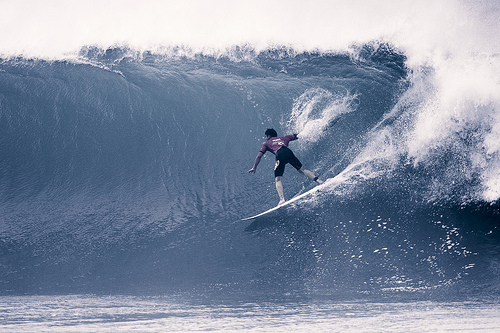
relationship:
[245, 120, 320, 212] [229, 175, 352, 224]
man on surfboard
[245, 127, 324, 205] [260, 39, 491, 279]
man riding wave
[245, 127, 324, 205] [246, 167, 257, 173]
man has hand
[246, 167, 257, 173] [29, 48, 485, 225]
hand inside wave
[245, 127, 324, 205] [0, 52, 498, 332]
man playing in water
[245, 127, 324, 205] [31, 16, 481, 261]
man surfing in ocean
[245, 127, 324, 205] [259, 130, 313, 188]
man wearing suit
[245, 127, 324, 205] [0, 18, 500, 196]
man riding wave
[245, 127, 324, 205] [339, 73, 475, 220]
man touching wave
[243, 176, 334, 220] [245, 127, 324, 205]
surfboard tethered to man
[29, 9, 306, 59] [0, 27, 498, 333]
skies over water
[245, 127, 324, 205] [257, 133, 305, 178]
man wearing suit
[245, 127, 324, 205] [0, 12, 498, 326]
man on wave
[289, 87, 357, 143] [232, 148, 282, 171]
white water formed by arm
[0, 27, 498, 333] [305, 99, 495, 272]
water on wave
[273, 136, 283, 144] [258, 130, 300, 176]
writing on clothing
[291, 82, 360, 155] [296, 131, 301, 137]
foam created by hand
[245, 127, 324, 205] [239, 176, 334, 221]
man standing on surfboard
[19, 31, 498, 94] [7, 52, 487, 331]
foam of wave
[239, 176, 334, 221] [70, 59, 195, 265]
surfboard on wave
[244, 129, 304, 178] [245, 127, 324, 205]
arms out on man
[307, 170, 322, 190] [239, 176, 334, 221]
strap attached to surfboard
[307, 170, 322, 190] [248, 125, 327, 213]
strap attached to man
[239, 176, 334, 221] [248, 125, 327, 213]
surfboard attached to man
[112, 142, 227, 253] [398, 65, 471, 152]
water from breaking wave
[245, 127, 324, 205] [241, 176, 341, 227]
man slanting downwards board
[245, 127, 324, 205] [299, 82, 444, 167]
man surfing wave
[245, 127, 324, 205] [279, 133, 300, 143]
man sticking out hand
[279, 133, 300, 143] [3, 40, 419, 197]
hand sticking in wave wall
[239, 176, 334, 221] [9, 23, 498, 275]
surfboard in wave